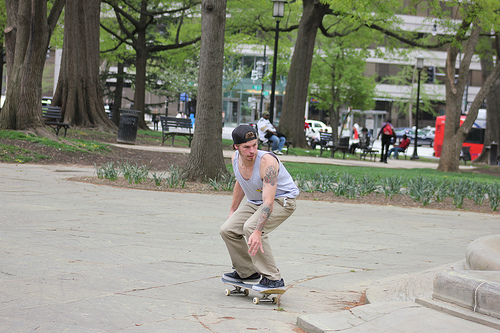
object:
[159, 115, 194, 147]
bench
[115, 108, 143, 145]
trash can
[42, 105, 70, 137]
bench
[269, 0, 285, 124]
lamp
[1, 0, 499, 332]
park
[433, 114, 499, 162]
bus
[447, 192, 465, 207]
plants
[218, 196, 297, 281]
pants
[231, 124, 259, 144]
hat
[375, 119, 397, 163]
person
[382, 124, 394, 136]
backpack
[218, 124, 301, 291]
man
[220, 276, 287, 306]
skate board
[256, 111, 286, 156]
person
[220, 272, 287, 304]
board